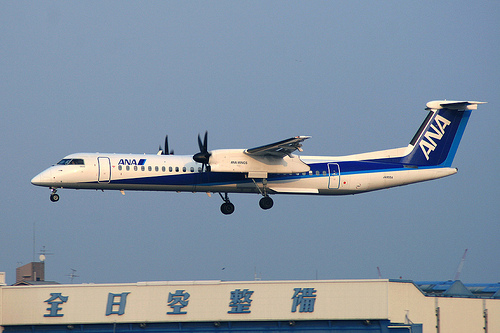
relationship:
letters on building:
[70, 275, 346, 330] [17, 216, 494, 330]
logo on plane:
[417, 106, 474, 179] [28, 99, 476, 222]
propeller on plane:
[181, 136, 226, 180] [29, 110, 426, 235]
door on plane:
[99, 158, 115, 187] [45, 103, 417, 210]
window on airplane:
[65, 150, 97, 169] [45, 95, 461, 239]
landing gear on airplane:
[200, 189, 298, 232] [26, 60, 430, 220]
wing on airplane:
[232, 131, 322, 173] [37, 101, 469, 301]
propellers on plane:
[153, 115, 248, 187] [96, 103, 446, 231]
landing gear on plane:
[219, 189, 281, 216] [23, 96, 433, 224]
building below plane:
[31, 251, 450, 329] [62, 103, 451, 223]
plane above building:
[43, 99, 491, 245] [42, 240, 452, 327]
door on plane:
[99, 158, 115, 187] [47, 111, 409, 229]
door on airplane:
[78, 152, 142, 199] [37, 71, 445, 256]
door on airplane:
[322, 159, 482, 183] [36, 83, 483, 217]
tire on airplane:
[40, 188, 65, 202] [30, 92, 483, 212]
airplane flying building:
[30, 92, 483, 212] [3, 243, 484, 328]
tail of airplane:
[415, 90, 484, 166] [31, 93, 481, 231]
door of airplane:
[99, 158, 115, 187] [30, 92, 483, 212]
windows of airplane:
[116, 164, 194, 174] [30, 92, 483, 212]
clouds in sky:
[259, 27, 342, 107] [8, 8, 467, 128]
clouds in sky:
[259, 27, 342, 107] [6, 6, 483, 99]